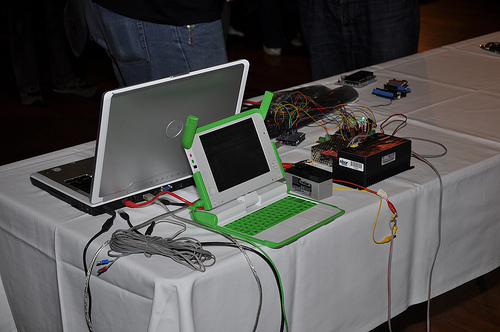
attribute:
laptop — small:
[153, 105, 367, 276]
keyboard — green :
[223, 185, 313, 244]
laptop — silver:
[22, 60, 250, 200]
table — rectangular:
[350, 52, 499, 229]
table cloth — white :
[102, 240, 252, 310]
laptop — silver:
[182, 87, 345, 247]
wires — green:
[227, 228, 470, 329]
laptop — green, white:
[157, 80, 356, 277]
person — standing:
[89, 11, 251, 108]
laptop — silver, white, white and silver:
[31, 58, 248, 217]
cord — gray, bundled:
[98, 214, 213, 271]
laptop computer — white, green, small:
[180, 87, 345, 247]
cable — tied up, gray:
[94, 215, 214, 285]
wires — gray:
[69, 187, 351, 329]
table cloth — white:
[285, 45, 486, 188]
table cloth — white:
[334, 27, 498, 214]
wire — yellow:
[328, 185, 399, 246]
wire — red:
[205, 230, 305, 318]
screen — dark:
[191, 120, 281, 200]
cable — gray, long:
[96, 225, 214, 277]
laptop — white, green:
[42, 56, 382, 273]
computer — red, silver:
[28, 57, 252, 219]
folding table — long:
[2, 30, 497, 330]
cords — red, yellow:
[337, 175, 400, 330]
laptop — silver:
[24, 47, 256, 210]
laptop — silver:
[28, 30, 381, 287]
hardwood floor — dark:
[398, 297, 493, 330]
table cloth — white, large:
[8, 41, 499, 328]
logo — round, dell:
[162, 115, 187, 142]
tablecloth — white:
[1, 30, 495, 330]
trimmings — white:
[31, 57, 251, 207]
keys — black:
[67, 173, 91, 193]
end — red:
[95, 266, 106, 275]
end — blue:
[93, 257, 109, 264]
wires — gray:
[106, 215, 214, 273]